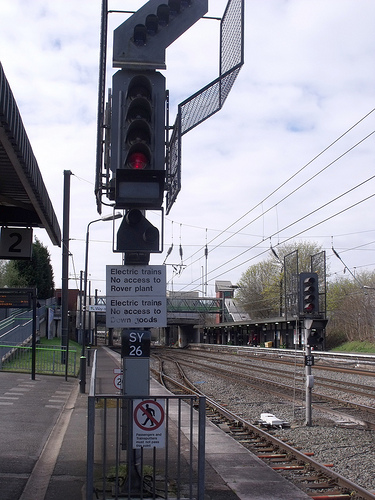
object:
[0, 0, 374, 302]
sky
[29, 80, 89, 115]
cloud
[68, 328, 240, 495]
walkway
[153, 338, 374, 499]
train track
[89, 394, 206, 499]
gate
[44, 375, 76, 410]
gutter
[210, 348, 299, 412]
curb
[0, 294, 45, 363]
road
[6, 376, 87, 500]
ground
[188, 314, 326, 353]
platform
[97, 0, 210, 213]
traffic light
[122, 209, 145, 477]
lightpost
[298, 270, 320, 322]
traffic light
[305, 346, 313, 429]
lightpost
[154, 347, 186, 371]
intersection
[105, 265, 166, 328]
sign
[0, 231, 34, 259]
sign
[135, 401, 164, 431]
no walking symbol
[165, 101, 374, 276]
wire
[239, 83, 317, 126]
cloud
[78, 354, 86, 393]
post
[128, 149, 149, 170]
stoplight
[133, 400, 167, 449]
sign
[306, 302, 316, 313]
stoplight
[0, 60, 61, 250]
roof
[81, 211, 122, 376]
street lamp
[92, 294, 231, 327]
walking bridge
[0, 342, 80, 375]
fence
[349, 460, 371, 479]
gravel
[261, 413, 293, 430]
control box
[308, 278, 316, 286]
light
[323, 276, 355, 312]
tree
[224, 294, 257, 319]
ramp